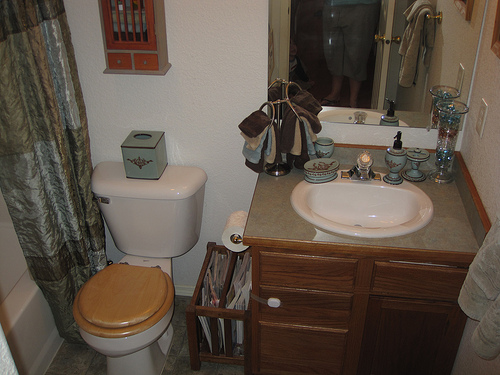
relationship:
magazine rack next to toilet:
[171, 229, 264, 374] [63, 143, 226, 370]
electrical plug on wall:
[472, 100, 487, 135] [458, 2, 497, 230]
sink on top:
[288, 166, 434, 239] [242, 142, 480, 252]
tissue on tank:
[119, 127, 169, 180] [91, 157, 203, 261]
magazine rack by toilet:
[183, 241, 257, 374] [64, 243, 198, 353]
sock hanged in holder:
[289, 116, 318, 156] [260, 78, 302, 178]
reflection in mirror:
[316, 5, 370, 108] [288, 5, 472, 145]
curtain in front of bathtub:
[0, 1, 108, 346] [3, 215, 73, 373]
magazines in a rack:
[185, 241, 247, 373] [183, 238, 250, 369]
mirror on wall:
[264, 0, 488, 152] [64, 1, 484, 285]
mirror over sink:
[264, 1, 484, 161] [245, 138, 484, 350]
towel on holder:
[257, 94, 321, 144] [260, 78, 297, 178]